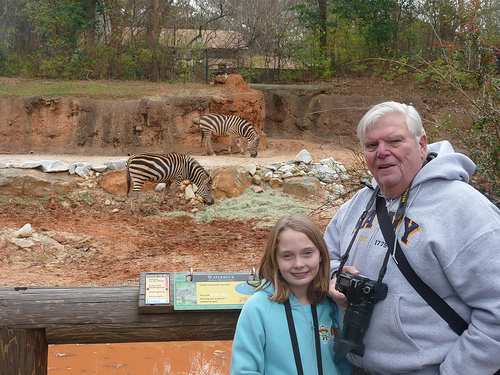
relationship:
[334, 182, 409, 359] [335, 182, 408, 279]
camera on strap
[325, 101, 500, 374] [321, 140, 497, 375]
man wearing sweat shirt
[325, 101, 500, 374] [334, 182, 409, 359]
man holding camera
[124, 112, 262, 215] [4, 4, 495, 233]
zebras at zoo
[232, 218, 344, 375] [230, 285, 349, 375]
girl wearing sweatshirt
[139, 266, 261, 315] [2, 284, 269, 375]
sign on fence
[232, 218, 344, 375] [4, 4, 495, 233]
girl at zoo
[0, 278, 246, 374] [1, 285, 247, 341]
round wooden railing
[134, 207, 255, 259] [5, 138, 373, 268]
hay on ground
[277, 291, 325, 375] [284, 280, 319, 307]
strap around neck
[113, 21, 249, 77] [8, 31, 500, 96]
building in distance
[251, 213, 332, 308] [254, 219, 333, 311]
hair medium length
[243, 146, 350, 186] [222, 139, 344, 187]
pile of rocks